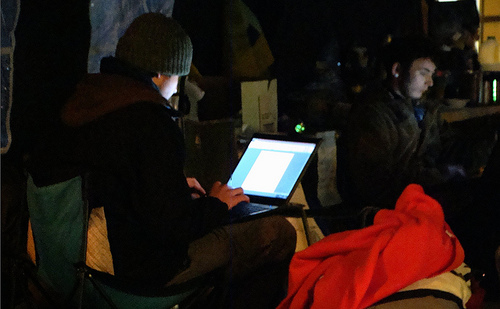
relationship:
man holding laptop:
[27, 14, 297, 308] [189, 133, 319, 223]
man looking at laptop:
[27, 14, 297, 308] [189, 133, 319, 223]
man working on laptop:
[27, 14, 297, 308] [189, 133, 319, 223]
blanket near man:
[271, 184, 467, 308] [27, 14, 297, 308]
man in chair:
[27, 14, 297, 308] [20, 159, 223, 308]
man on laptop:
[27, 14, 297, 308] [189, 133, 319, 223]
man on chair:
[27, 14, 297, 308] [20, 159, 223, 308]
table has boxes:
[276, 104, 499, 136] [469, 73, 499, 106]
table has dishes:
[276, 104, 499, 136] [445, 95, 471, 108]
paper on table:
[315, 132, 344, 204] [276, 104, 499, 136]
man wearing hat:
[27, 14, 297, 308] [113, 12, 192, 75]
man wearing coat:
[27, 14, 297, 308] [32, 75, 229, 290]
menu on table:
[239, 79, 280, 135] [276, 104, 499, 136]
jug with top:
[478, 35, 499, 76] [486, 35, 495, 41]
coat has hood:
[32, 75, 229, 290] [55, 73, 171, 127]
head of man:
[112, 12, 192, 102] [27, 14, 297, 308]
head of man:
[384, 36, 441, 102] [338, 34, 494, 209]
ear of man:
[392, 62, 402, 79] [338, 34, 494, 209]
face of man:
[156, 69, 179, 101] [27, 14, 297, 308]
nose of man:
[426, 78, 433, 88] [338, 34, 494, 209]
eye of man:
[419, 70, 427, 76] [338, 34, 494, 209]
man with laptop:
[27, 14, 297, 308] [189, 133, 319, 223]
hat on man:
[113, 12, 192, 75] [27, 14, 297, 308]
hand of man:
[209, 180, 248, 211] [27, 14, 297, 308]